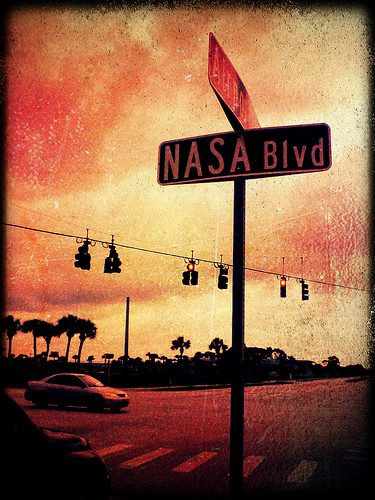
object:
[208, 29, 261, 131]
signs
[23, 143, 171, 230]
sky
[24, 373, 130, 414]
car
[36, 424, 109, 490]
camera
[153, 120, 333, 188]
street sign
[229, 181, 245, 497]
pole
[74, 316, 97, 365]
tree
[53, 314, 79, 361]
tree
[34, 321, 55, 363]
tree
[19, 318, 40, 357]
tree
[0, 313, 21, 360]
tree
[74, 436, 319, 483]
white lines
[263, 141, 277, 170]
letter b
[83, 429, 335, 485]
paint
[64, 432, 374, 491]
crosswalk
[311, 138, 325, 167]
letter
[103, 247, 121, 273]
traffic signal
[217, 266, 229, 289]
traffic signal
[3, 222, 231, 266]
line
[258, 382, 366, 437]
floor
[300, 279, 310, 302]
stoplights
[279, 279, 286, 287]
red lights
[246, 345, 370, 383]
buildings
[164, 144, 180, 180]
letters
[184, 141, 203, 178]
letters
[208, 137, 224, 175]
letters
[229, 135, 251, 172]
letters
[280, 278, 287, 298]
light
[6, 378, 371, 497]
ground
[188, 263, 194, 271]
light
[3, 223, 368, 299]
rope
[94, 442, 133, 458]
line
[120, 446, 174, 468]
line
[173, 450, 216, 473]
line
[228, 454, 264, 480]
line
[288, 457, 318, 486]
line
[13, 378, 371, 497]
road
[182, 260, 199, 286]
light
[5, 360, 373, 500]
city street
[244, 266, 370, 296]
line